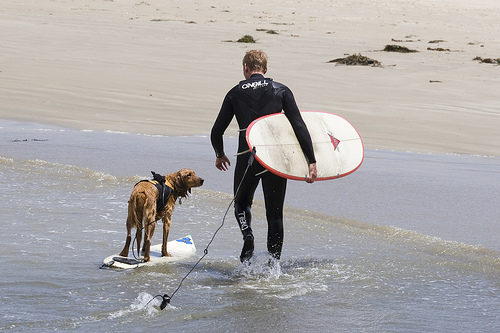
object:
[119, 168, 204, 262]
dog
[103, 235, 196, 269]
surfboard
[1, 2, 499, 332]
sand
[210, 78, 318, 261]
suit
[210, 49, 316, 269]
man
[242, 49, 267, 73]
hair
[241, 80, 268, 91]
symbol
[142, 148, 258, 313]
cable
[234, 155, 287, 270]
leg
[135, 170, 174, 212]
life jacket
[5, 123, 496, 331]
water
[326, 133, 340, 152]
logo